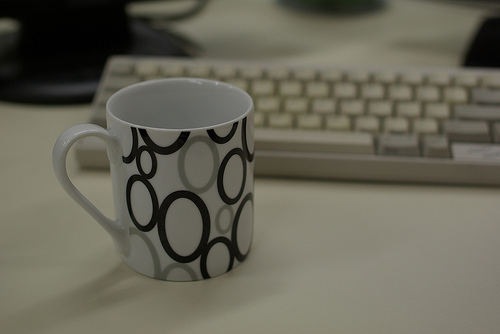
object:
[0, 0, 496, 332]
table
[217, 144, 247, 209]
circle art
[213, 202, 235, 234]
circle art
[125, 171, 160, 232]
circle art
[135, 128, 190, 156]
circle art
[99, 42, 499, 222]
keyboard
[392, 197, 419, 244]
ground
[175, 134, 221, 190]
grey circle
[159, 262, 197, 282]
grey circle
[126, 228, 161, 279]
grey circle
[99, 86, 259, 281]
cup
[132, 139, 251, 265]
circles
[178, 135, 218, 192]
circle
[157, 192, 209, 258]
circle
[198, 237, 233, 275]
circle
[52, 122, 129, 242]
handle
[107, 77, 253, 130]
top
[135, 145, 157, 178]
circle